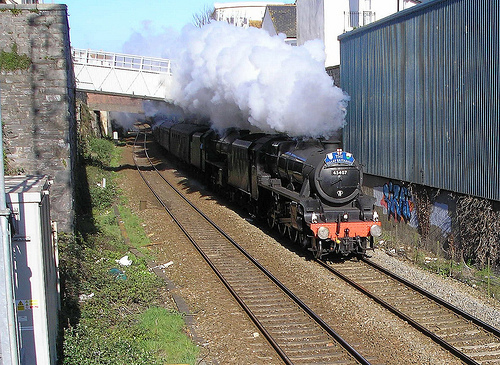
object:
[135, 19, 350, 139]
steam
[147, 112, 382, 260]
train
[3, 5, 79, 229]
brick wall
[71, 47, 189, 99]
bridge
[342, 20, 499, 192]
metal wall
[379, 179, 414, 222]
graffiti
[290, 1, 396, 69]
white house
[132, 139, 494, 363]
train track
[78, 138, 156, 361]
grass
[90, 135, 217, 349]
ground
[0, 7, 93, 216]
fence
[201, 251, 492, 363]
tracks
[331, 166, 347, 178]
numbers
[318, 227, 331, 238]
light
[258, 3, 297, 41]
roof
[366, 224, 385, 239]
light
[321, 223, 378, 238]
front of train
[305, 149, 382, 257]
train car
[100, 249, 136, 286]
trash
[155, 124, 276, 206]
train cars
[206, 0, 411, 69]
building